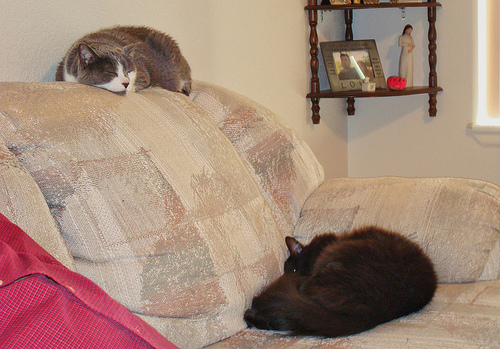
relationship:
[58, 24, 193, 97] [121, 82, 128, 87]
cat has nose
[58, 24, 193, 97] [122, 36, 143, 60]
cat has ear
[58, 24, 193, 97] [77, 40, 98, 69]
cat has ear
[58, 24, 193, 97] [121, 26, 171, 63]
cat has fur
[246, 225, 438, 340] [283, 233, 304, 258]
black cat has ear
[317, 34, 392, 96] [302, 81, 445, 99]
picture frame on shelf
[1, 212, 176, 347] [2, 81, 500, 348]
material on couch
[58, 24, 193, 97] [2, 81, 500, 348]
cat on couch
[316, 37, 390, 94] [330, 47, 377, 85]
frame with picture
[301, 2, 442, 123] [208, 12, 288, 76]
shelf on wall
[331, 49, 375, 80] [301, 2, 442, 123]
framed photo on shelf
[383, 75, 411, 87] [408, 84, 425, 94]
object on shelf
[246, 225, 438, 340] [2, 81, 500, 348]
black cat on couch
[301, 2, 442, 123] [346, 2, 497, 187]
shelf on wall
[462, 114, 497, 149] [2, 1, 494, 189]
window sill on wall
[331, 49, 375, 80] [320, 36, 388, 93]
framed photo on frame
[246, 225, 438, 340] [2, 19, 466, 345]
black cat laying on couch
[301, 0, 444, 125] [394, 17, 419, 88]
shelf with a figurine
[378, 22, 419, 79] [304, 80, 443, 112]
figurine on shelf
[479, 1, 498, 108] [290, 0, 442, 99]
window beside shelf